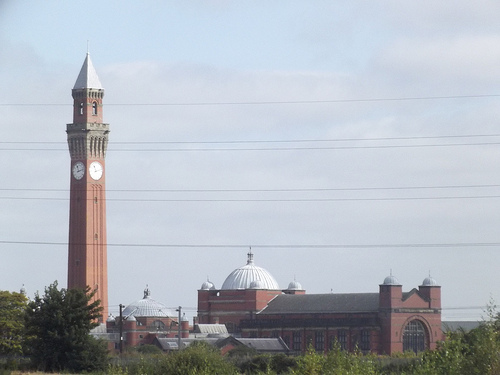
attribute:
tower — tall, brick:
[57, 41, 116, 330]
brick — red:
[71, 213, 97, 238]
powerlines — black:
[13, 107, 499, 252]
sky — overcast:
[1, 3, 474, 272]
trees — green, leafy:
[5, 290, 94, 374]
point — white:
[74, 42, 101, 91]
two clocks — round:
[68, 161, 107, 178]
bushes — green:
[299, 332, 496, 373]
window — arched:
[401, 319, 434, 353]